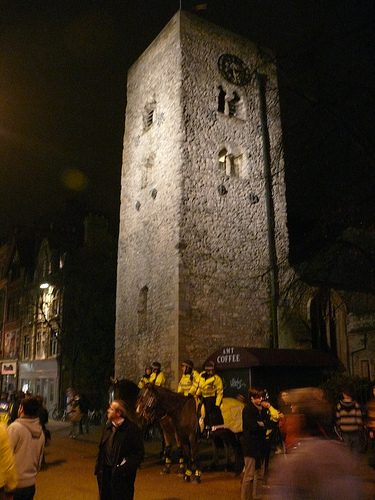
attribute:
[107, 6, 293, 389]
tower — stone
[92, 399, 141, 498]
man — looking, standing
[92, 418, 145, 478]
jacket — black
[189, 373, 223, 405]
jacket — yellow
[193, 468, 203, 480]
bootie — yellow, reflective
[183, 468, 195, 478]
bootie — yellow, reflective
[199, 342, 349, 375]
awning — canopy, brown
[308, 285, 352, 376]
entrance — archway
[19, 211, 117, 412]
house — old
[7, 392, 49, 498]
person — man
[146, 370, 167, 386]
jacket — yellow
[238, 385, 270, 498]
man — standing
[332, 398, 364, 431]
hoodie — striped, sweatshirt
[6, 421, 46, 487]
hoodie — white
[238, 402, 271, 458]
coat — black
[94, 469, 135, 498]
pants — black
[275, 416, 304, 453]
dress — red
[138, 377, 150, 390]
vest — yellow